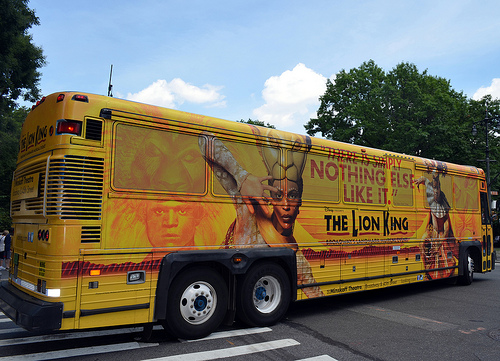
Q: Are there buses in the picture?
A: Yes, there is a bus.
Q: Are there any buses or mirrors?
A: Yes, there is a bus.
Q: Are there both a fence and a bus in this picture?
A: No, there is a bus but no fences.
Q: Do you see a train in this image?
A: No, there are no trains.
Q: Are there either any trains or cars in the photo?
A: No, there are no trains or cars.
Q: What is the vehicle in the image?
A: The vehicle is a bus.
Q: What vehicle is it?
A: The vehicle is a bus.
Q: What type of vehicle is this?
A: This is a bus.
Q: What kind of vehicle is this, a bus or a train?
A: This is a bus.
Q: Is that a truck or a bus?
A: That is a bus.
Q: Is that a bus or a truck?
A: That is a bus.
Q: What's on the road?
A: The bus is on the road.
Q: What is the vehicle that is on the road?
A: The vehicle is a bus.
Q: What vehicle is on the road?
A: The vehicle is a bus.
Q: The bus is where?
A: The bus is on the road.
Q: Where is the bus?
A: The bus is on the road.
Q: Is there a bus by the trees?
A: Yes, there is a bus by the trees.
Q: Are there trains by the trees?
A: No, there is a bus by the trees.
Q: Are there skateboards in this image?
A: No, there are no skateboards.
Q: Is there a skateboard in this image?
A: No, there are no skateboards.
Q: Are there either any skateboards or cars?
A: No, there are no skateboards or cars.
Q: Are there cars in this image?
A: No, there are no cars.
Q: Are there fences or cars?
A: No, there are no cars or fences.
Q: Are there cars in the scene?
A: No, there are no cars.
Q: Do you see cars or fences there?
A: No, there are no cars or fences.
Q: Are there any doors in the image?
A: Yes, there are doors.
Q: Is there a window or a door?
A: Yes, there are doors.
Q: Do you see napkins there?
A: No, there are no napkins.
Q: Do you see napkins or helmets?
A: No, there are no napkins or helmets.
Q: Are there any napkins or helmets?
A: No, there are no napkins or helmets.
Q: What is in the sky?
A: The clouds are in the sky.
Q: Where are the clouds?
A: The clouds are in the sky.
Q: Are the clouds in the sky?
A: Yes, the clouds are in the sky.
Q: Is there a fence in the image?
A: No, there are no fences.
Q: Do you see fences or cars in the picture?
A: No, there are no fences or cars.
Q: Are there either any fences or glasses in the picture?
A: No, there are no fences or glasses.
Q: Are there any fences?
A: No, there are no fences.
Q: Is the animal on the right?
A: Yes, the animal is on the right of the image.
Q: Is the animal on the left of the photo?
A: No, the animal is on the right of the image.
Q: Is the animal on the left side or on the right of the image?
A: The animal is on the right of the image.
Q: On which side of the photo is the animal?
A: The animal is on the right of the image.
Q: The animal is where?
A: The animal is on the bus.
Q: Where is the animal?
A: The animal is on the bus.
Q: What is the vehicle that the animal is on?
A: The vehicle is a bus.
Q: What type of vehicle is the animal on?
A: The animal is on the bus.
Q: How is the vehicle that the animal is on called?
A: The vehicle is a bus.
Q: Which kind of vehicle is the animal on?
A: The animal is on the bus.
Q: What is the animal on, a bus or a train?
A: The animal is on a bus.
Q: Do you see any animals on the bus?
A: Yes, there is an animal on the bus.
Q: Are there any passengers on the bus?
A: No, there is an animal on the bus.